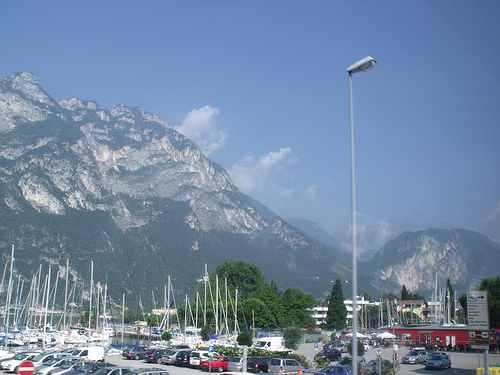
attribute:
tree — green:
[323, 277, 350, 332]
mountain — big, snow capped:
[11, 70, 483, 316]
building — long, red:
[383, 324, 483, 349]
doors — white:
[444, 331, 454, 346]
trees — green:
[169, 260, 312, 330]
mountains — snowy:
[0, 85, 218, 209]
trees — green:
[229, 253, 302, 337]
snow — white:
[53, 125, 200, 212]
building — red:
[383, 298, 493, 346]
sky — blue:
[365, 41, 480, 206]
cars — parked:
[137, 317, 273, 368]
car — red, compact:
[197, 332, 231, 370]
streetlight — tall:
[320, 36, 385, 262]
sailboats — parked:
[2, 251, 253, 351]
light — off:
[343, 41, 399, 106]